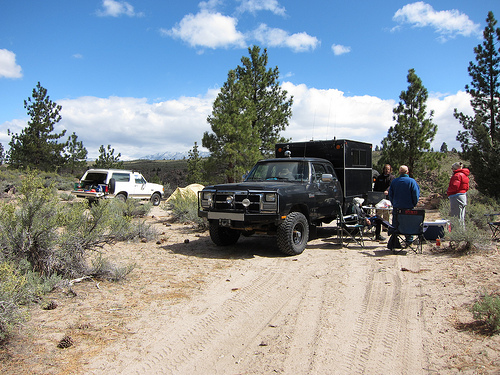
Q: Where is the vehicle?
A: On the road.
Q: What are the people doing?
A: Standing on the side of the road.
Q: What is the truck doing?
A: The truck is parked.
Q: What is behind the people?
A: Trees.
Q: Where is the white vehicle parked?
A: To the left of the black truck.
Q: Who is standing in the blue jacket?
A: A man.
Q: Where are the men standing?
A: In a wooded area.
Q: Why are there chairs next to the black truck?
A: To allow for seating options.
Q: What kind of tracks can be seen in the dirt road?
A: Tire tracks.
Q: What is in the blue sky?
A: Fluffy white clouds.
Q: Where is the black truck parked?
A: On a dirt road.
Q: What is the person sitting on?
A: A chair.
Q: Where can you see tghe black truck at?
A: Next to the three men.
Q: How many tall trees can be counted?
A: Four.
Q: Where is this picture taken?
A: Dirt road.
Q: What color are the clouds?
A: White.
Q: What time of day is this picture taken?
A: Day time.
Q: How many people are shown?
A: Three.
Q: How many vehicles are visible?
A: Two.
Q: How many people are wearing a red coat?
A: One.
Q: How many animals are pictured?
A: Zero.